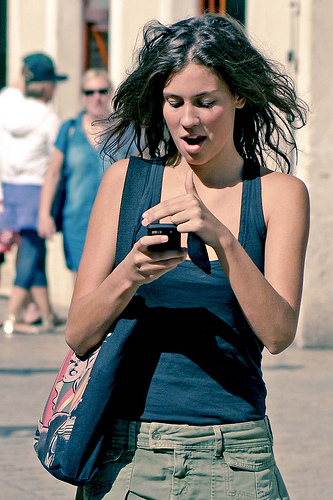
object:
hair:
[88, 9, 315, 178]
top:
[112, 153, 269, 428]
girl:
[63, 9, 312, 500]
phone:
[146, 222, 182, 252]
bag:
[31, 315, 139, 488]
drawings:
[66, 388, 73, 395]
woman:
[37, 51, 145, 290]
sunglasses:
[83, 87, 110, 95]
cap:
[20, 49, 69, 89]